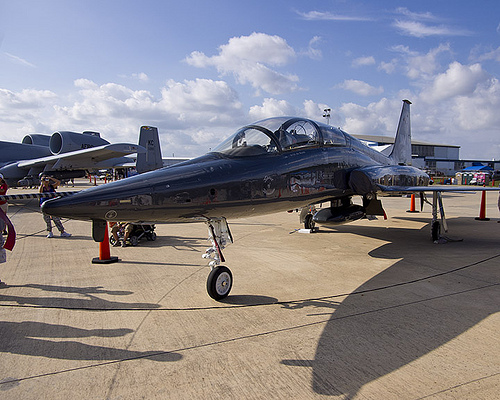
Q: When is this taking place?
A: Daylight.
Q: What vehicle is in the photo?
A: Plane.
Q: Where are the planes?
A: Cement tarmac.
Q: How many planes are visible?
A: Three.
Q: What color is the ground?
A: Tan.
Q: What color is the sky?
A: Blue and white.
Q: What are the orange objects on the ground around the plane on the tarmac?
A: Cones.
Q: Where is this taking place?
A: At the space station.